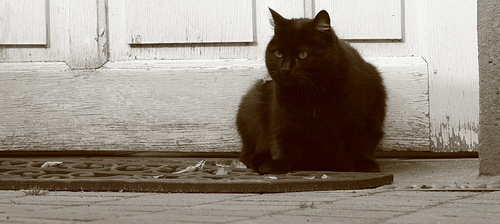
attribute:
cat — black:
[244, 0, 398, 172]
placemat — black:
[6, 136, 381, 198]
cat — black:
[194, 0, 434, 175]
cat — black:
[235, 7, 389, 174]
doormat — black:
[0, 152, 396, 194]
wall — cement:
[475, 1, 498, 178]